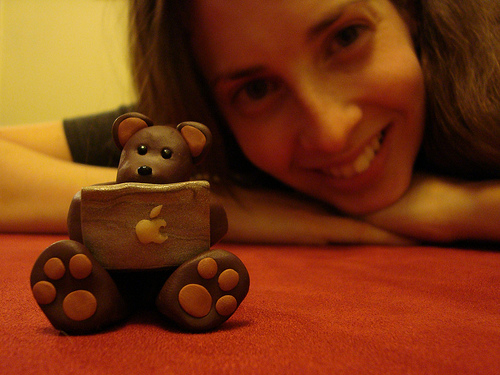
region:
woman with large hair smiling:
[0, 6, 496, 239]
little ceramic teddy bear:
[33, 116, 247, 339]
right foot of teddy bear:
[163, 255, 253, 331]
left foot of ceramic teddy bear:
[31, 239, 114, 333]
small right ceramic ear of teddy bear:
[178, 124, 205, 158]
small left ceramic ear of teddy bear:
[117, 114, 149, 147]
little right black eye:
[324, 22, 369, 67]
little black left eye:
[236, 73, 278, 108]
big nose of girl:
[291, 75, 362, 159]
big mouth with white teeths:
[307, 118, 392, 192]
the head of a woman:
[145, 4, 451, 238]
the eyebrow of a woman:
[207, 28, 263, 83]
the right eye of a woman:
[216, 78, 273, 110]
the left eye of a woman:
[314, 26, 371, 58]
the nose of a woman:
[293, 79, 360, 154]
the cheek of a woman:
[347, 48, 424, 103]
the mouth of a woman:
[299, 143, 389, 192]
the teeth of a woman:
[327, 159, 372, 180]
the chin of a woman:
[340, 180, 416, 223]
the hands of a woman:
[272, 199, 470, 261]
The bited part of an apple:
[153, 218, 173, 246]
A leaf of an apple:
[145, 202, 171, 221]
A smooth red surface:
[332, 314, 404, 352]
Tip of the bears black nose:
[147, 164, 155, 175]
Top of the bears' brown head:
[152, 123, 184, 133]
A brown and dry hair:
[447, 14, 493, 94]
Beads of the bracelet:
[192, 172, 229, 186]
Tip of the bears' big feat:
[40, 233, 78, 268]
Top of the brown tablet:
[80, 175, 210, 207]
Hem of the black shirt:
[53, 114, 80, 159]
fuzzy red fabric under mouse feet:
[0, 235, 495, 367]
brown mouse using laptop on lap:
[75, 111, 215, 261]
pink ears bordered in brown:
[90, 105, 205, 175]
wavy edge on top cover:
[76, 175, 207, 265]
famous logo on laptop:
[76, 180, 211, 266]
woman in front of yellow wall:
[1, 1, 491, 241]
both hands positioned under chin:
[0, 11, 496, 246]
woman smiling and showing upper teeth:
[200, 0, 431, 211]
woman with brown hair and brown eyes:
[130, 1, 495, 206]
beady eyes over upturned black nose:
[125, 135, 171, 180]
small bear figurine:
[28, 110, 263, 341]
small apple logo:
[126, 199, 176, 249]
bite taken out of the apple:
[158, 223, 168, 236]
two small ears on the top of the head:
[106, 105, 211, 156]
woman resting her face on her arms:
[0, 0, 497, 261]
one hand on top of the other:
[258, 179, 466, 257]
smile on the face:
[293, 126, 396, 183]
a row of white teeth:
[317, 133, 391, 177]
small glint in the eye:
[138, 143, 145, 149]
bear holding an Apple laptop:
[21, 103, 270, 338]